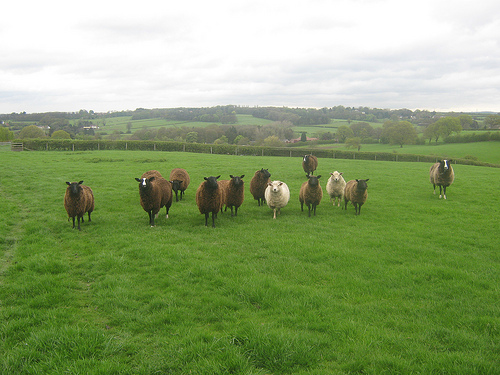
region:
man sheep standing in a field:
[45, 133, 467, 250]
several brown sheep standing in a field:
[57, 158, 273, 225]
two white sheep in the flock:
[249, 163, 354, 210]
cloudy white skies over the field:
[245, 42, 367, 90]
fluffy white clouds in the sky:
[351, 65, 430, 99]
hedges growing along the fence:
[21, 135, 416, 159]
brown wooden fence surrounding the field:
[1, 138, 31, 150]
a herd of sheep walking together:
[57, 135, 459, 235]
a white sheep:
[263, 175, 291, 220]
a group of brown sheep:
[59, 168, 276, 223]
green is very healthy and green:
[3, 145, 496, 371]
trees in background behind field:
[2, 103, 497, 163]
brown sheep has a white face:
[132, 175, 157, 196]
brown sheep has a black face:
[200, 171, 221, 191]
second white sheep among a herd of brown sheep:
[325, 166, 352, 211]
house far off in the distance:
[37, 120, 105, 142]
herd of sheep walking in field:
[60, 148, 458, 234]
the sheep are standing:
[8, 95, 459, 290]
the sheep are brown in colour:
[67, 129, 248, 229]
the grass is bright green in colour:
[106, 256, 433, 291]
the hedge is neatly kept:
[116, 139, 274, 162]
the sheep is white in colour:
[261, 176, 291, 218]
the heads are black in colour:
[203, 165, 242, 200]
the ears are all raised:
[171, 140, 341, 206]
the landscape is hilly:
[55, 89, 332, 159]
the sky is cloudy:
[76, 10, 327, 92]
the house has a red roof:
[270, 133, 325, 145]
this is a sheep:
[39, 167, 113, 235]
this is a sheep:
[124, 160, 175, 222]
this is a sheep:
[162, 165, 198, 207]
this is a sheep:
[189, 161, 233, 237]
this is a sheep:
[212, 152, 249, 221]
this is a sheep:
[241, 156, 281, 205]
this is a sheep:
[338, 171, 376, 218]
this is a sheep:
[287, 133, 331, 183]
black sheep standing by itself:
[63, 179, 93, 229]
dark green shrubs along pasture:
[12, 139, 461, 163]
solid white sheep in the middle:
[264, 180, 290, 217]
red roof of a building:
[291, 135, 318, 140]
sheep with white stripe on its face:
[429, 157, 453, 197]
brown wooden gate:
[11, 140, 23, 150]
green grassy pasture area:
[3, 148, 495, 368]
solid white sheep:
[327, 170, 344, 206]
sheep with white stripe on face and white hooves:
[136, 175, 171, 227]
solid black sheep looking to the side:
[250, 168, 270, 205]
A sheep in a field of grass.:
[298, 172, 325, 219]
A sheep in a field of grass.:
[136, 173, 178, 225]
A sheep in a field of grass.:
[170, 167, 186, 191]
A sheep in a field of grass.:
[194, 178, 221, 224]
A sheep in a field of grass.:
[251, 166, 272, 205]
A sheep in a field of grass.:
[296, 152, 318, 177]